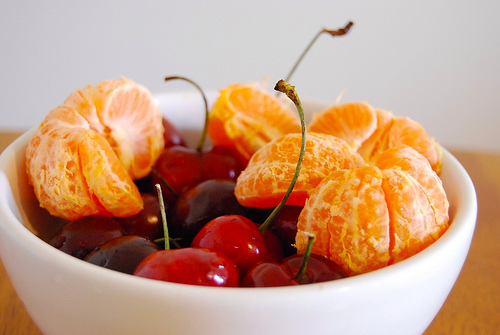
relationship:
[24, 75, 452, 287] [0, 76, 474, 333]
fruit in bowl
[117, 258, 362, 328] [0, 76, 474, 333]
edge of bowl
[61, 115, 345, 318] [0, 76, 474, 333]
cherries in bowl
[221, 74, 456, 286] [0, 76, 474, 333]
oranges in bowl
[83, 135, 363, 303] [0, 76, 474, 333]
cherries in bowl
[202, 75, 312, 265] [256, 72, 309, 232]
cherry with stem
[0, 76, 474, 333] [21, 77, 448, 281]
bowl of fruit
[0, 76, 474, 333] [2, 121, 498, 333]
bowl on table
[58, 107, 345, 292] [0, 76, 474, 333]
cherries in bowl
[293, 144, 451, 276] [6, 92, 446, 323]
oranges in bowl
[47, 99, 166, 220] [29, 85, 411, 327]
oranges in bowl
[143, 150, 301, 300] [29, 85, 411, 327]
cherries in bowl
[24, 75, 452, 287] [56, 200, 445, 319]
fruit in bowl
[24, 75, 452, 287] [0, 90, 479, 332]
fruit in bowl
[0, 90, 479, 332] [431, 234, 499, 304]
bowl on table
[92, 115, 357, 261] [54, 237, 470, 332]
fruit in bowl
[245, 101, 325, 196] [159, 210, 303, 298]
stem on cherry